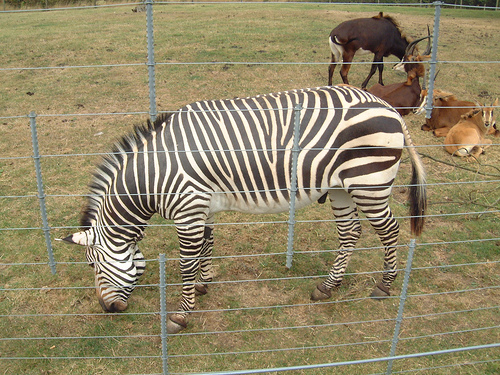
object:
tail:
[401, 117, 428, 235]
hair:
[406, 173, 428, 234]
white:
[200, 189, 343, 214]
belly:
[205, 175, 344, 213]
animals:
[367, 35, 434, 118]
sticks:
[398, 152, 500, 221]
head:
[59, 227, 149, 314]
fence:
[0, 102, 500, 375]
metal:
[156, 253, 168, 374]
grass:
[0, 0, 500, 374]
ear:
[63, 229, 94, 247]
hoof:
[166, 313, 186, 334]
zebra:
[62, 83, 427, 334]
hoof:
[194, 284, 208, 295]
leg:
[164, 216, 207, 309]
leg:
[324, 190, 362, 284]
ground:
[0, 0, 500, 375]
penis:
[316, 192, 328, 204]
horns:
[420, 22, 432, 56]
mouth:
[106, 300, 125, 314]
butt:
[329, 29, 351, 65]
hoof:
[310, 285, 332, 300]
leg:
[345, 191, 399, 284]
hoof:
[370, 285, 389, 300]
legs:
[179, 211, 200, 247]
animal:
[444, 97, 499, 158]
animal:
[420, 94, 475, 137]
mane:
[76, 113, 171, 231]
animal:
[328, 13, 432, 91]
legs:
[340, 55, 354, 79]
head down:
[391, 53, 424, 76]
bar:
[29, 111, 58, 276]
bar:
[145, 14, 156, 126]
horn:
[405, 35, 434, 56]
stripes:
[140, 110, 393, 207]